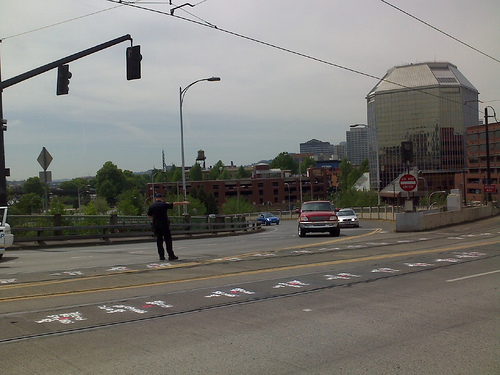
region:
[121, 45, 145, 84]
first stop light on pole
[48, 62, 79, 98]
second stoplight on pole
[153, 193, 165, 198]
man wearing black hat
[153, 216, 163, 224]
man wearing black shirt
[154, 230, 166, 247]
man wearing black jeans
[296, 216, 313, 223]
light on left of car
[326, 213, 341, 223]
light on right of car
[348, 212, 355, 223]
silver car in back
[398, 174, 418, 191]
street sign in traffic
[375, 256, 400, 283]
white markings on street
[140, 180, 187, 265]
Cop directing traffic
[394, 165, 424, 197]
Do not enter traffic sign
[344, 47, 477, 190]
large glass building in the background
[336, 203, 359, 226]
silver car on the highway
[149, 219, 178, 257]
cop wearing black uniform pants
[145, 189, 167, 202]
person wearing a hat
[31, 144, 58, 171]
triangle traffic sign on a pole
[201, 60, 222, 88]
street lamp on a pole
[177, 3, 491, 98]
electric lines above the trees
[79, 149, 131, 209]
Trees with leaves on them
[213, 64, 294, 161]
blue and white sky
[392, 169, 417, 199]
red and white sign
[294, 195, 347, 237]
large red pickup truck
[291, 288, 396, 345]
road is light grey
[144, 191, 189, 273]
police officer in road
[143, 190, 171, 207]
officer has black cap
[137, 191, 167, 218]
officer has black shirt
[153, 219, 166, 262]
officer has black pants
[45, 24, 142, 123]
black traffic lights on pole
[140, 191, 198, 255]
officer directing traffic on the street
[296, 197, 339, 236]
red truck on the strett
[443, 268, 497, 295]
white line painted on the street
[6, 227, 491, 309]
yellow double lines on the street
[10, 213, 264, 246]
railings along the street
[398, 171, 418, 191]
red and white traffic sign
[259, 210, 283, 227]
blue car on the street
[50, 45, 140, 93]
two black traffic signals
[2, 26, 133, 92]
black bar traffic signals are on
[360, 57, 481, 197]
tallest building in the cityscape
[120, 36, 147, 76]
black traffic light hanging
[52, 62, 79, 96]
black traffic light hanging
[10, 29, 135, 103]
long metal light pole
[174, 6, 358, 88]
wire in the air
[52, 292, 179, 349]
white writing on the street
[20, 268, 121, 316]
yellow lines on street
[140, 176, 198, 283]
man standing in middle of road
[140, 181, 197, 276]
man directing traffic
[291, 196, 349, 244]
red front to car on street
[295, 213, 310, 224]
Headlight of a truck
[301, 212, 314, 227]
Headlight of a red truck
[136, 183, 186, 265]
man in black outfit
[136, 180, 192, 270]
man in black outfit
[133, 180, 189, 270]
man standing on street